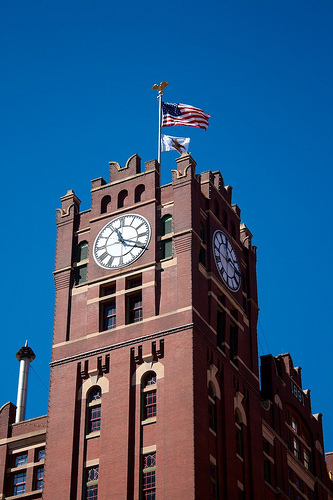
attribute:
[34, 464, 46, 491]
window — red, white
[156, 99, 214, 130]
flag — blue, white, red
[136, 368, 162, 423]
window — white, red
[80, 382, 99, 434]
window — red, white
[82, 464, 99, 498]
window — white, red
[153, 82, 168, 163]
pole — flag, silver, tall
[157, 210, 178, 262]
window — arched 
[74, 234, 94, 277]
window — arched 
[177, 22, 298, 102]
sky — blue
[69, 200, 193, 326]
frames — red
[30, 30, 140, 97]
sky — clear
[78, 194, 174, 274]
time — says 11:20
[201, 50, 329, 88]
sky — blue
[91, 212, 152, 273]
clock — white 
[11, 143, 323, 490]
building — brown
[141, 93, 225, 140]
flag — U.S.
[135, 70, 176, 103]
eagle — gold